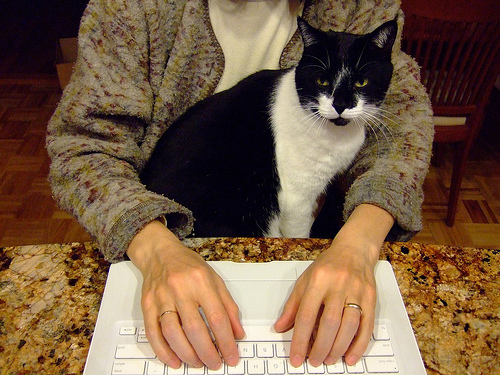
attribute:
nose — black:
[330, 100, 348, 117]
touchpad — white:
[215, 257, 292, 324]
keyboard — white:
[90, 310, 406, 372]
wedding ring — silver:
[344, 302, 361, 313]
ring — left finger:
[342, 298, 367, 313]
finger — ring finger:
[320, 285, 363, 374]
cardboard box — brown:
[46, 33, 74, 82]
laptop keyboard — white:
[104, 317, 399, 374]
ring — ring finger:
[158, 310, 175, 318]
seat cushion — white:
[432, 115, 469, 132]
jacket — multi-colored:
[45, 0, 433, 263]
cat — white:
[131, 14, 431, 256]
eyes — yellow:
[306, 68, 375, 93]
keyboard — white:
[85, 293, 412, 373]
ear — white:
[373, 17, 400, 47]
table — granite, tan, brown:
[4, 220, 496, 372]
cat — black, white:
[138, 23, 406, 244]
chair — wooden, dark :
[401, 5, 498, 227]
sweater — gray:
[43, 1, 436, 265]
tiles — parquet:
[419, 138, 498, 239]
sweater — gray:
[22, 5, 482, 267]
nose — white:
[329, 101, 351, 116]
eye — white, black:
[351, 75, 372, 89]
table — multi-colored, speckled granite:
[2, 236, 499, 373]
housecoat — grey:
[43, 2, 435, 237]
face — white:
[295, 14, 406, 135]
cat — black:
[122, 15, 402, 243]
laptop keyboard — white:
[81, 255, 428, 373]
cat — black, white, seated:
[137, 14, 399, 234]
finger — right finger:
[156, 297, 199, 368]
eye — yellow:
[312, 74, 330, 85]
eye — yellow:
[350, 75, 370, 90]